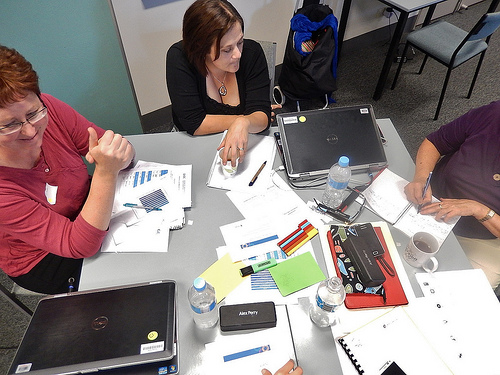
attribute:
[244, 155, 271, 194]
pen — brown , small 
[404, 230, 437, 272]
cup — white coffe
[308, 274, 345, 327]
warter bottle — two warter 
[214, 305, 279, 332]
eyeglass case — eye glass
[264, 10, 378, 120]
bookbag — black , blue 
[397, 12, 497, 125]
chair — blue , grey 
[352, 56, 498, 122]
floor — white 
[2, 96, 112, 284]
shirt — pink